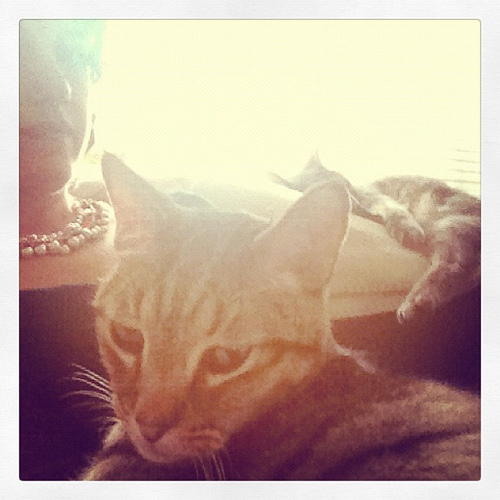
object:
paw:
[395, 300, 419, 327]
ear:
[256, 175, 351, 295]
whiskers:
[59, 360, 117, 412]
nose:
[133, 390, 180, 445]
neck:
[17, 180, 90, 228]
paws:
[388, 220, 428, 246]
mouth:
[18, 112, 76, 141]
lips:
[18, 118, 73, 135]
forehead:
[89, 236, 322, 354]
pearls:
[34, 243, 48, 257]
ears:
[96, 149, 182, 251]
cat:
[55, 148, 480, 479]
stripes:
[160, 269, 187, 330]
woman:
[19, 19, 178, 480]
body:
[18, 198, 132, 481]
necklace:
[17, 191, 112, 260]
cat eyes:
[191, 341, 252, 379]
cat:
[266, 150, 480, 326]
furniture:
[90, 176, 479, 386]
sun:
[73, 21, 480, 206]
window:
[74, 20, 480, 188]